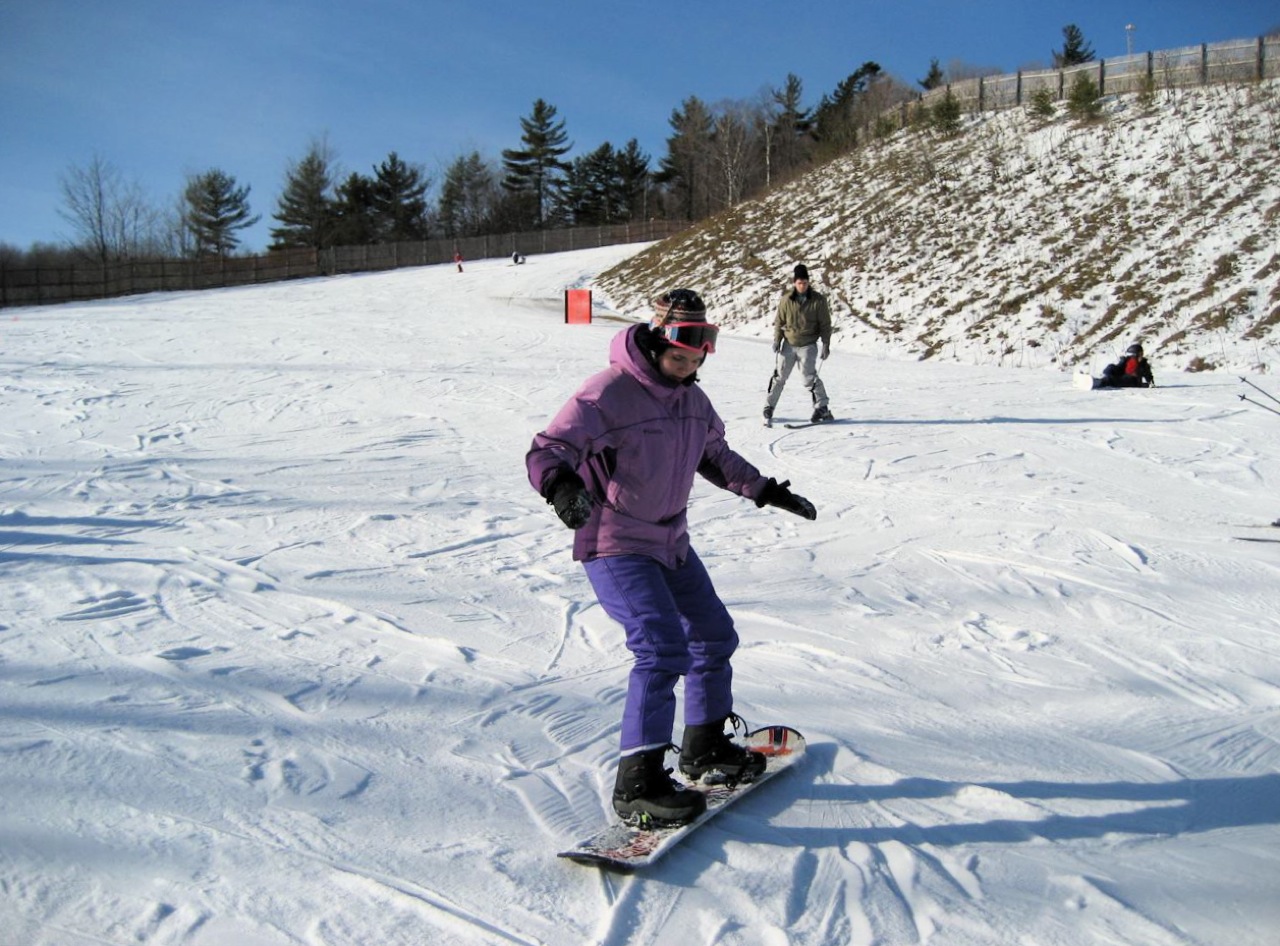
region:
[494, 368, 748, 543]
woman wearing a purple jacket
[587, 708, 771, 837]
woman wearing black shoes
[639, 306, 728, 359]
woman wearing pink ski goggles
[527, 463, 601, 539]
woman wearing black gloves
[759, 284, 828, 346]
person wearing a green jacket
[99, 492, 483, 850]
tracks on the snow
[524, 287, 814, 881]
girl on a white snowboard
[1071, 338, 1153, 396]
person sitting in the snow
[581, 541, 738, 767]
purple pants on the girl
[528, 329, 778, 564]
pink coat on the girl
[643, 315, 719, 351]
pink goggles on the girl's head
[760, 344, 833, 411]
tan pants on the man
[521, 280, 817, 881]
snow boarder going down the hill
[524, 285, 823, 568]
a woman wearing a pink coat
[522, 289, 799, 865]
a woman standing on a snowboard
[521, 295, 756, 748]
a woman wearing purple ski pants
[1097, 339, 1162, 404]
a person sitting down on the snow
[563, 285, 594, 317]
an orange marker on a ski trail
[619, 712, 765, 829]
black and grey snowboard boots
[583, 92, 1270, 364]
snow and grass on a hillside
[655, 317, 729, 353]
goggles on the face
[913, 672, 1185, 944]
snow on the ground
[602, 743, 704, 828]
ski boot on right foot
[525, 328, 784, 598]
purple jacket on person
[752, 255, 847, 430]
man standing on snow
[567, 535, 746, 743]
purple pants on person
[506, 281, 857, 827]
woman balancing on snowboard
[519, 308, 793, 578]
woman wearing big coat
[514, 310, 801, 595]
woman's coatis purple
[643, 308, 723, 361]
woman wearing goggles on her head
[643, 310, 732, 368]
woman's goggles are pink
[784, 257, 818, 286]
man's cap is black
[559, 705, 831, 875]
snowboard is orange and white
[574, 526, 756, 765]
woman's pants are purple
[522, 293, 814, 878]
someone is in the snow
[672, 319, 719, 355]
goggles on the head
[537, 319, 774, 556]
the jacket is pink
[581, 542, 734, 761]
the pants are purple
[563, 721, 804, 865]
snow board on ground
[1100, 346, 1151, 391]
person is lying down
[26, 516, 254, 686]
white snow with streak marks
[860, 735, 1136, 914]
white snow with streak marks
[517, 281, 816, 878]
female riding a snowboard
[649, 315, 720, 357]
orange rimmed ski glasses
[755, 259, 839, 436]
a man is skiing slowly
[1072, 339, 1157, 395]
a person on a snowboard has fallen down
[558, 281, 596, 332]
an orange trail marker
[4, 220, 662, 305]
long stretch of safety fencing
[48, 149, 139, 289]
a tall tree with no leaves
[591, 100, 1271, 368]
a partially snow covered hillside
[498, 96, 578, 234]
a very tall pine tree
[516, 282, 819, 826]
girl is on the snowboard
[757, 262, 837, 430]
guy is riding skies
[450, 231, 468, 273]
person is in the snow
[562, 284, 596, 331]
red sign is in the snow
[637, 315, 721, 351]
goggles are on little girls head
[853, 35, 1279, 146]
fence is at the top of the hill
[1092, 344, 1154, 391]
person is sitting in the snow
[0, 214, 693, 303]
fence is a long the snow trail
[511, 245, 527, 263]
person is sitting in the snow